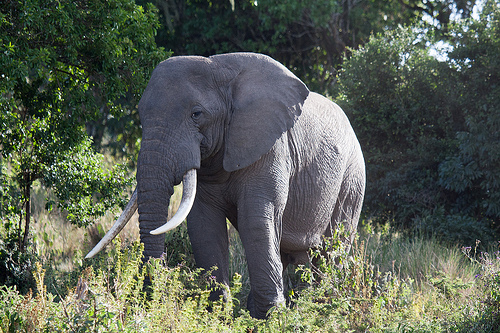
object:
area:
[14, 73, 439, 316]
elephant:
[84, 51, 365, 320]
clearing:
[1, 151, 496, 332]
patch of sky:
[395, 1, 498, 75]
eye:
[191, 111, 203, 119]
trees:
[327, 2, 494, 221]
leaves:
[0, 0, 55, 42]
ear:
[210, 51, 310, 171]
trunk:
[136, 121, 178, 301]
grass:
[1, 167, 500, 333]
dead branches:
[275, 18, 358, 72]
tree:
[1, 0, 126, 274]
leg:
[235, 191, 285, 321]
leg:
[186, 193, 234, 312]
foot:
[245, 296, 291, 320]